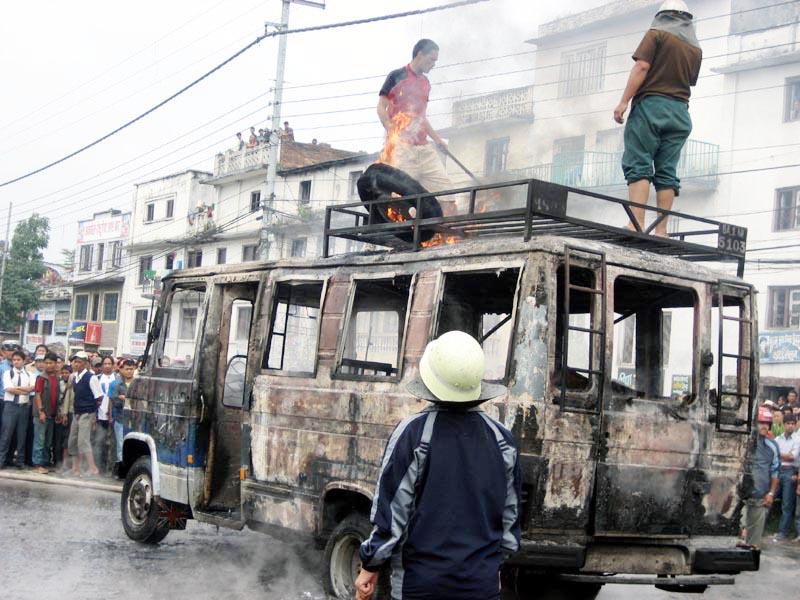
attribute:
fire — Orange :
[369, 99, 493, 247]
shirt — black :
[378, 64, 432, 139]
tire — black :
[115, 459, 169, 547]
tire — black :
[315, 514, 382, 598]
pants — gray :
[2, 404, 39, 464]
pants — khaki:
[67, 417, 95, 475]